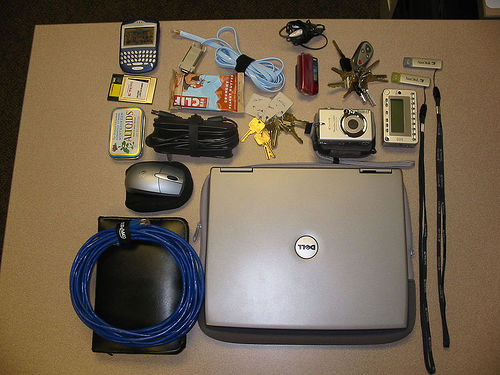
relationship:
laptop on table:
[203, 165, 417, 345] [7, 18, 499, 374]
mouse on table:
[122, 161, 191, 208] [7, 18, 499, 374]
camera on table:
[316, 108, 376, 146] [7, 18, 499, 374]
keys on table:
[328, 40, 389, 107] [7, 18, 499, 374]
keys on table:
[240, 100, 306, 159] [7, 18, 499, 374]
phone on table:
[118, 17, 160, 73] [7, 18, 499, 374]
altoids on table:
[110, 109, 143, 159] [7, 18, 499, 374]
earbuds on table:
[282, 20, 326, 50] [7, 18, 499, 374]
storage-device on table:
[404, 56, 442, 72] [7, 18, 499, 374]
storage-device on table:
[392, 72, 430, 87] [7, 18, 499, 374]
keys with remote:
[328, 40, 389, 107] [352, 41, 373, 70]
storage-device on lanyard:
[404, 56, 442, 72] [433, 69, 451, 346]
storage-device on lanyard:
[392, 72, 430, 87] [420, 102, 435, 374]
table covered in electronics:
[7, 18, 499, 374] [70, 21, 450, 368]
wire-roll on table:
[213, 29, 285, 91] [7, 18, 499, 374]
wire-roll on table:
[70, 216, 206, 346] [7, 18, 499, 374]